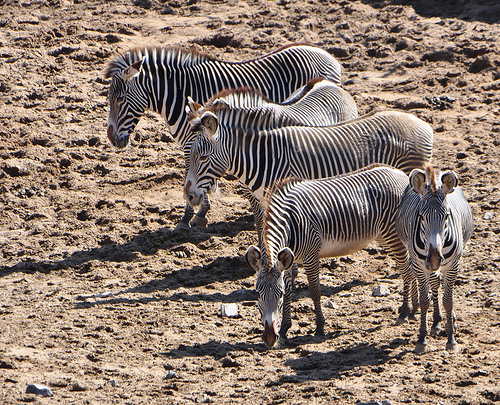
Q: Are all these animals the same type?
A: Yes, all the animals are zebras.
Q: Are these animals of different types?
A: No, all the animals are zebras.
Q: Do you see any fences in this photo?
A: No, there are no fences.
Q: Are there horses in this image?
A: No, there are no horses.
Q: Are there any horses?
A: No, there are no horses.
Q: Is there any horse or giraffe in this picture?
A: No, there are no horses or giraffes.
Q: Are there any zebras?
A: Yes, there is a zebra.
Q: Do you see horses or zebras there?
A: Yes, there is a zebra.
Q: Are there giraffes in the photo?
A: No, there are no giraffes.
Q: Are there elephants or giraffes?
A: No, there are no giraffes or elephants.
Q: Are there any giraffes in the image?
A: No, there are no giraffes.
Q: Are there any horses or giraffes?
A: No, there are no giraffes or horses.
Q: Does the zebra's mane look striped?
A: Yes, the mane is striped.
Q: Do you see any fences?
A: No, there are no fences.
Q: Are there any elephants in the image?
A: No, there are no elephants.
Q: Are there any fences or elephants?
A: No, there are no elephants or fences.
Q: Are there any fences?
A: No, there are no fences.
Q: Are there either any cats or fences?
A: No, there are no fences or cats.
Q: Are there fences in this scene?
A: No, there are no fences.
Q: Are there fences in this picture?
A: No, there are no fences.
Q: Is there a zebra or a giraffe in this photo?
A: Yes, there is a zebra.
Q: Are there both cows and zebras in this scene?
A: No, there is a zebra but no cows.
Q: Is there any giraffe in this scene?
A: No, there are no giraffes.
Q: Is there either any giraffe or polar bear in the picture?
A: No, there are no giraffes or polar bears.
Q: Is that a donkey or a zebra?
A: That is a zebra.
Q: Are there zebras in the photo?
A: Yes, there is a zebra.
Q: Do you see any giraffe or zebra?
A: Yes, there is a zebra.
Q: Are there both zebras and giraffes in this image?
A: No, there is a zebra but no giraffes.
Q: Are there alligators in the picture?
A: No, there are no alligators.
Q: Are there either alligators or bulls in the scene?
A: No, there are no alligators or bulls.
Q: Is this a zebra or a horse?
A: This is a zebra.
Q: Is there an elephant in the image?
A: No, there are no elephants.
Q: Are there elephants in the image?
A: No, there are no elephants.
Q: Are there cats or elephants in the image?
A: No, there are no elephants or cats.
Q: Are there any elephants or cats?
A: No, there are no elephants or cats.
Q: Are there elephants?
A: No, there are no elephants.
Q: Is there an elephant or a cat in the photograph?
A: No, there are no elephants or cats.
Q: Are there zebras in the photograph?
A: Yes, there is a zebra.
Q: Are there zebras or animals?
A: Yes, there is a zebra.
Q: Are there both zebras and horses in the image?
A: No, there is a zebra but no horses.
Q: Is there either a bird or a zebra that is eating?
A: Yes, the zebra is eating.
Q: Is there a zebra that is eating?
A: Yes, there is a zebra that is eating.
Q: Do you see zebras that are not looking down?
A: Yes, there is a zebra that is eating .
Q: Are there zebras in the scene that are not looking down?
A: Yes, there is a zebra that is eating.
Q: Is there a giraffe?
A: No, there are no giraffes.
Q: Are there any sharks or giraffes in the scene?
A: No, there are no giraffes or sharks.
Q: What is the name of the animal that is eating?
A: The animal is a zebra.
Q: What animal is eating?
A: The animal is a zebra.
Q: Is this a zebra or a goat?
A: This is a zebra.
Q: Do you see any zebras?
A: Yes, there is a zebra.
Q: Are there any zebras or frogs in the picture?
A: Yes, there is a zebra.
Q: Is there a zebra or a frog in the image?
A: Yes, there is a zebra.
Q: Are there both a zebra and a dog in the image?
A: No, there is a zebra but no dogs.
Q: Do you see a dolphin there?
A: No, there are no dolphins.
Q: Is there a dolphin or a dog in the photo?
A: No, there are no dolphins or dogs.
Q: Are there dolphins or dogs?
A: No, there are no dolphins or dogs.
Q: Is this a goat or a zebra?
A: This is a zebra.